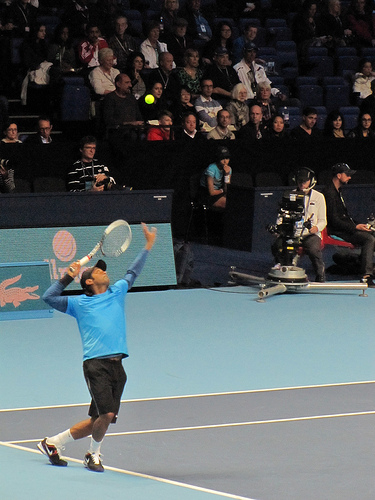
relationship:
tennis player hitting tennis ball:
[37, 223, 158, 474] [145, 94, 154, 104]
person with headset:
[269, 167, 328, 282] [290, 167, 317, 193]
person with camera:
[269, 167, 328, 282] [264, 195, 310, 265]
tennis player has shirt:
[37, 223, 158, 474] [39, 250, 149, 361]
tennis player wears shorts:
[37, 223, 158, 474] [83, 359, 127, 424]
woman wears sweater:
[2, 121, 26, 180] [67, 160, 116, 192]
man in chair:
[321, 162, 374, 288] [321, 228, 358, 272]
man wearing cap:
[321, 162, 374, 288] [331, 162, 357, 177]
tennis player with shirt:
[37, 223, 158, 474] [39, 250, 149, 361]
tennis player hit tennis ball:
[37, 223, 158, 474] [145, 94, 154, 104]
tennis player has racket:
[37, 223, 158, 474] [70, 219, 134, 272]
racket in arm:
[70, 219, 134, 272] [41, 261, 81, 316]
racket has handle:
[70, 219, 134, 272] [70, 243, 101, 271]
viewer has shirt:
[198, 147, 232, 209] [199, 164, 231, 190]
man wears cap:
[321, 162, 374, 288] [331, 162, 357, 177]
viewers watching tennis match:
[0, 0, 373, 207] [1, 218, 373, 499]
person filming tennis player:
[269, 167, 328, 282] [37, 223, 158, 474]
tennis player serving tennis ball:
[37, 223, 158, 474] [145, 94, 154, 104]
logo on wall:
[0, 273, 41, 309] [0, 190, 177, 292]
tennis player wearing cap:
[37, 223, 158, 474] [81, 259, 108, 289]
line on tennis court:
[0, 380, 374, 413] [0, 280, 373, 499]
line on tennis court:
[2, 410, 375, 446] [0, 280, 373, 499]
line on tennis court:
[0, 440, 252, 499] [0, 280, 373, 499]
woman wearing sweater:
[2, 121, 26, 180] [67, 160, 116, 192]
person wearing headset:
[269, 167, 328, 282] [290, 167, 317, 193]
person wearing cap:
[269, 167, 328, 282] [299, 170, 310, 182]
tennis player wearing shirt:
[37, 223, 158, 474] [39, 250, 149, 361]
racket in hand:
[70, 219, 134, 272] [66, 260, 80, 278]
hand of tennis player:
[66, 260, 80, 278] [37, 223, 158, 474]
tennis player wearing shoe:
[37, 223, 158, 474] [37, 437, 69, 467]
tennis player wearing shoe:
[37, 223, 158, 474] [84, 453, 105, 473]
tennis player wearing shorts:
[37, 223, 158, 474] [83, 359, 127, 424]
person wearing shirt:
[269, 167, 328, 282] [303, 189, 326, 238]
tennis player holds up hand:
[37, 223, 158, 474] [66, 260, 80, 278]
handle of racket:
[70, 243, 101, 271] [70, 219, 134, 272]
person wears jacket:
[269, 167, 328, 282] [304, 188, 326, 238]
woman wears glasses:
[2, 121, 26, 180] [8, 127, 17, 133]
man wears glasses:
[24, 118, 66, 175] [39, 127, 51, 133]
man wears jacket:
[321, 162, 374, 288] [321, 180, 356, 238]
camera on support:
[264, 195, 310, 265] [228, 264, 369, 303]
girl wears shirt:
[198, 147, 232, 209] [199, 164, 231, 190]